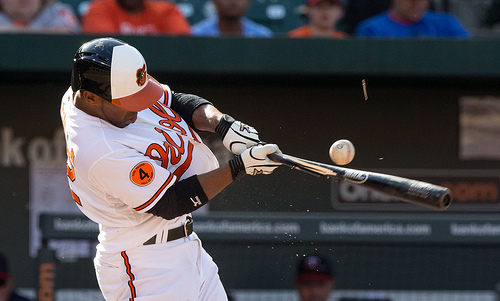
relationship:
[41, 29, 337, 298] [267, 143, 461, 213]
player holding bat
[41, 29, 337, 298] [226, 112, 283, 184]
player wearing gloves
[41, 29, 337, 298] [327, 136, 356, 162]
player hits ball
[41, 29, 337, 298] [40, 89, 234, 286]
player wearing uniform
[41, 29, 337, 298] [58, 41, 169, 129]
player wearing helmet